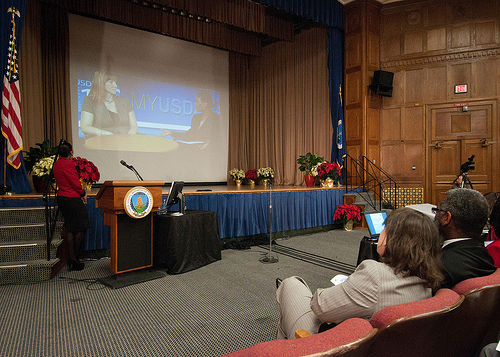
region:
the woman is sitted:
[269, 219, 416, 309]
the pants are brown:
[280, 281, 312, 321]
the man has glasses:
[436, 193, 499, 297]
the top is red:
[53, 160, 86, 201]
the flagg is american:
[6, 19, 30, 166]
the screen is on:
[72, 20, 237, 180]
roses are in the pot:
[333, 198, 363, 220]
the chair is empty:
[227, 318, 377, 355]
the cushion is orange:
[297, 329, 357, 346]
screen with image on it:
[58, 25, 229, 177]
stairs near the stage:
[7, 199, 57, 272]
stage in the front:
[109, 167, 281, 189]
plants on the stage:
[224, 153, 345, 189]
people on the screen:
[86, 70, 218, 136]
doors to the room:
[428, 97, 496, 192]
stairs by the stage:
[339, 155, 395, 211]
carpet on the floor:
[6, 293, 241, 345]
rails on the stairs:
[348, 153, 397, 198]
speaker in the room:
[368, 61, 403, 104]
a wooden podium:
[97, 176, 164, 278]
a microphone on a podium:
[119, 158, 145, 179]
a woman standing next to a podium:
[53, 140, 90, 272]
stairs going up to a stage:
[0, 190, 66, 282]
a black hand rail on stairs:
[38, 137, 63, 263]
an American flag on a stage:
[1, 7, 24, 170]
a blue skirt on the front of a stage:
[84, 185, 370, 257]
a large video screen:
[64, 8, 232, 185]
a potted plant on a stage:
[293, 151, 322, 184]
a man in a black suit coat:
[431, 185, 493, 289]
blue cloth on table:
[195, 185, 334, 220]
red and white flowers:
[224, 154, 277, 194]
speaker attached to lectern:
[122, 157, 149, 182]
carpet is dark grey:
[108, 290, 168, 348]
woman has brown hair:
[55, 145, 71, 158]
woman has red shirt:
[53, 159, 79, 201]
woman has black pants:
[60, 199, 82, 250]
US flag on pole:
[0, 5, 35, 164]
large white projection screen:
[61, 27, 239, 184]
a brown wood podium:
[98, 176, 164, 279]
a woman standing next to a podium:
[54, 141, 96, 273]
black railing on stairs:
[42, 133, 71, 255]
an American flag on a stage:
[0, 22, 25, 169]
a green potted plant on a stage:
[294, 150, 322, 186]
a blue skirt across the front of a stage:
[86, 184, 372, 254]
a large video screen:
[63, 12, 236, 190]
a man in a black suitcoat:
[432, 236, 497, 289]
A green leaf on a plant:
[300, 159, 307, 164]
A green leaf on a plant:
[306, 162, 310, 166]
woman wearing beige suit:
[272, 206, 444, 340]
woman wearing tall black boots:
[50, 139, 90, 271]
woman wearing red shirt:
[52, 138, 90, 270]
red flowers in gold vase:
[72, 153, 100, 193]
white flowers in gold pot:
[229, 165, 245, 188]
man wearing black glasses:
[430, 187, 497, 287]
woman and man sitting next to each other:
[276, 186, 494, 338]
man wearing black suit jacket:
[428, 186, 497, 296]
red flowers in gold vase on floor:
[331, 198, 363, 232]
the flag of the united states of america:
[0, 3, 28, 153]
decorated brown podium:
[105, 166, 167, 285]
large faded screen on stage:
[71, 19, 243, 184]